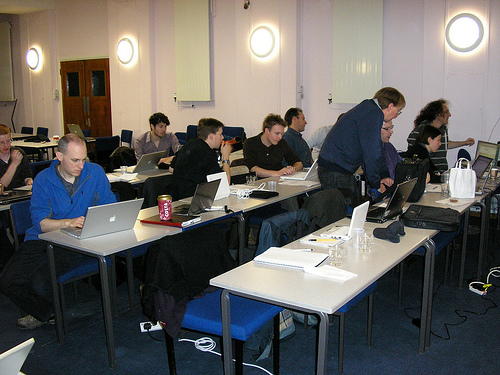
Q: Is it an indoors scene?
A: Yes, it is indoors.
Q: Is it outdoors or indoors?
A: It is indoors.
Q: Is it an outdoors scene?
A: No, it is indoors.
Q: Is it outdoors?
A: No, it is indoors.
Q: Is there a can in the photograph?
A: Yes, there is a can.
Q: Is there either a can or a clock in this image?
A: Yes, there is a can.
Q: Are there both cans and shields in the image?
A: No, there is a can but no shields.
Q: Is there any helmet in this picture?
A: No, there are no helmets.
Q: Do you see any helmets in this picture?
A: No, there are no helmets.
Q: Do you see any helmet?
A: No, there are no helmets.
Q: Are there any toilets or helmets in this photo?
A: No, there are no helmets or toilets.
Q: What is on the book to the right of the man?
A: The can is on the book.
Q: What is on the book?
A: The can is on the book.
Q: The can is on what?
A: The can is on the book.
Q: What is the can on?
A: The can is on the book.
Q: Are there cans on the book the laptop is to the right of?
A: Yes, there is a can on the book.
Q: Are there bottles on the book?
A: No, there is a can on the book.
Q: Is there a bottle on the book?
A: No, there is a can on the book.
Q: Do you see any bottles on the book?
A: No, there is a can on the book.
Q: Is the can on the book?
A: Yes, the can is on the book.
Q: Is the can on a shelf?
A: No, the can is on the book.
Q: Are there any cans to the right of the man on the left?
A: Yes, there is a can to the right of the man.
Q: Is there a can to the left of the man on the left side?
A: No, the can is to the right of the man.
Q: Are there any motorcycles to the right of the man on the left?
A: No, there is a can to the right of the man.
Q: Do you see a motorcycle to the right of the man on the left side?
A: No, there is a can to the right of the man.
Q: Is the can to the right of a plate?
A: No, the can is to the right of the man.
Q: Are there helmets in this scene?
A: No, there are no helmets.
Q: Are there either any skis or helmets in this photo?
A: No, there are no helmets or skis.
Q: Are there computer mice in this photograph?
A: No, there are no computer mice.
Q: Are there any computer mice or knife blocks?
A: No, there are no computer mice or knife blocks.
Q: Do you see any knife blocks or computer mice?
A: No, there are no computer mice or knife blocks.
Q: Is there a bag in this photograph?
A: Yes, there is a bag.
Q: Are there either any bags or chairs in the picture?
A: Yes, there is a bag.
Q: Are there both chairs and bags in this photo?
A: Yes, there are both a bag and a chair.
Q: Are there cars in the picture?
A: No, there are no cars.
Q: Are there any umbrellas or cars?
A: No, there are no cars or umbrellas.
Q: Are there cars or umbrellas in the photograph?
A: No, there are no cars or umbrellas.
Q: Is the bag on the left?
A: No, the bag is on the right of the image.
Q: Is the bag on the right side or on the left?
A: The bag is on the right of the image.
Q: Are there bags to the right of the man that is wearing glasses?
A: Yes, there is a bag to the right of the man.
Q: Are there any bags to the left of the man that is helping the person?
A: No, the bag is to the right of the man.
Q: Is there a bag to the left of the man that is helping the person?
A: No, the bag is to the right of the man.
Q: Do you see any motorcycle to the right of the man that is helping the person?
A: No, there is a bag to the right of the man.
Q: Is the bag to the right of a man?
A: Yes, the bag is to the right of a man.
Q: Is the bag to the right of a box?
A: No, the bag is to the right of a man.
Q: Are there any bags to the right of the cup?
A: No, the bag is to the left of the cup.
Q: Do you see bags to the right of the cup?
A: No, the bag is to the left of the cup.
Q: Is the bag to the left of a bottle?
A: No, the bag is to the left of a cup.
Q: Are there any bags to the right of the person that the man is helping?
A: Yes, there is a bag to the right of the person.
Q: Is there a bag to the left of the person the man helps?
A: No, the bag is to the right of the person.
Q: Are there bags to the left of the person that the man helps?
A: No, the bag is to the right of the person.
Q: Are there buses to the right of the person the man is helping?
A: No, there is a bag to the right of the person.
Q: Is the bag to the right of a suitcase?
A: No, the bag is to the right of a person.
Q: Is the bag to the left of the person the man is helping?
A: No, the bag is to the right of the person.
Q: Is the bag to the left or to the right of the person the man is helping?
A: The bag is to the right of the person.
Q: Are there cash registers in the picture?
A: No, there are no cash registers.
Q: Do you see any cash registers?
A: No, there are no cash registers.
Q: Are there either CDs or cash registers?
A: No, there are no cash registers or cds.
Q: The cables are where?
A: The cables are on the floor.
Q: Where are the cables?
A: The cables are on the floor.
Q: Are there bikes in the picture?
A: No, there are no bikes.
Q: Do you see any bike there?
A: No, there are no bikes.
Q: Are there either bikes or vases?
A: No, there are no bikes or vases.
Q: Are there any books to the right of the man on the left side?
A: Yes, there is a book to the right of the man.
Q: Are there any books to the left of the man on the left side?
A: No, the book is to the right of the man.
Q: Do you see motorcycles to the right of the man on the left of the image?
A: No, there is a book to the right of the man.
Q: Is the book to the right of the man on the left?
A: Yes, the book is to the right of the man.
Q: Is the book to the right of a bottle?
A: No, the book is to the right of the man.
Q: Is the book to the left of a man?
A: No, the book is to the right of a man.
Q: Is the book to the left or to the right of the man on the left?
A: The book is to the right of the man.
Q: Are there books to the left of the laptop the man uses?
A: Yes, there is a book to the left of the laptop.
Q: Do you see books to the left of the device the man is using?
A: Yes, there is a book to the left of the laptop.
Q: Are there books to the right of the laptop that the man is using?
A: No, the book is to the left of the laptop computer.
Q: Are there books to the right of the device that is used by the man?
A: No, the book is to the left of the laptop computer.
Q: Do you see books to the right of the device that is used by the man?
A: No, the book is to the left of the laptop computer.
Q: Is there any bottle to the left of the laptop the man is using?
A: No, there is a book to the left of the laptop.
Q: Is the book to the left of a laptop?
A: Yes, the book is to the left of a laptop.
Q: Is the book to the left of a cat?
A: No, the book is to the left of a laptop.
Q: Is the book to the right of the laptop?
A: No, the book is to the left of the laptop.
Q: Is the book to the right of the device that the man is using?
A: No, the book is to the left of the laptop.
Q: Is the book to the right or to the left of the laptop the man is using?
A: The book is to the left of the laptop.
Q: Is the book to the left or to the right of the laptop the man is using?
A: The book is to the left of the laptop.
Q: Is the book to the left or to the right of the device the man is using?
A: The book is to the left of the laptop.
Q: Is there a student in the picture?
A: Yes, there is a student.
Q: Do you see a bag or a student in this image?
A: Yes, there is a student.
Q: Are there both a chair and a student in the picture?
A: Yes, there are both a student and a chair.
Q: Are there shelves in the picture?
A: No, there are no shelves.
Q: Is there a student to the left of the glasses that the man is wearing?
A: Yes, there is a student to the left of the glasses.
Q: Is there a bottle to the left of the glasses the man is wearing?
A: No, there is a student to the left of the glasses.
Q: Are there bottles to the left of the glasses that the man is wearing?
A: No, there is a student to the left of the glasses.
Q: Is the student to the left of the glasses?
A: Yes, the student is to the left of the glasses.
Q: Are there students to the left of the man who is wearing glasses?
A: Yes, there is a student to the left of the man.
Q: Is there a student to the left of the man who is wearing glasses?
A: Yes, there is a student to the left of the man.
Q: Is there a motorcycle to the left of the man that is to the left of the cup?
A: No, there is a student to the left of the man.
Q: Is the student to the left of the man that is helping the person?
A: Yes, the student is to the left of the man.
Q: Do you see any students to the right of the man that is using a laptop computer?
A: Yes, there is a student to the right of the man.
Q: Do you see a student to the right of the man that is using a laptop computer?
A: Yes, there is a student to the right of the man.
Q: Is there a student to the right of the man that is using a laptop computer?
A: Yes, there is a student to the right of the man.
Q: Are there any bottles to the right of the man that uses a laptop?
A: No, there is a student to the right of the man.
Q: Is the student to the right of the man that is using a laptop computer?
A: Yes, the student is to the right of the man.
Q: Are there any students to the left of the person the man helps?
A: Yes, there is a student to the left of the person.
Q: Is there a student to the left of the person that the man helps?
A: Yes, there is a student to the left of the person.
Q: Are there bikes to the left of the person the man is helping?
A: No, there is a student to the left of the person.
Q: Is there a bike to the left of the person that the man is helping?
A: No, there is a student to the left of the person.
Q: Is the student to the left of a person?
A: Yes, the student is to the left of a person.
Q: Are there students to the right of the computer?
A: Yes, there is a student to the right of the computer.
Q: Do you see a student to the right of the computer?
A: Yes, there is a student to the right of the computer.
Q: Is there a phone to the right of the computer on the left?
A: No, there is a student to the right of the computer.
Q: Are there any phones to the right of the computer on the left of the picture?
A: No, there is a student to the right of the computer.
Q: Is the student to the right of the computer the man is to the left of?
A: Yes, the student is to the right of the computer.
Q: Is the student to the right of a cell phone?
A: No, the student is to the right of the computer.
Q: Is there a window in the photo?
A: Yes, there are windows.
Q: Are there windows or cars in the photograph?
A: Yes, there are windows.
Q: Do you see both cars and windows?
A: No, there are windows but no cars.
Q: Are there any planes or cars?
A: No, there are no cars or planes.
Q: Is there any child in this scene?
A: Yes, there are children.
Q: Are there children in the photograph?
A: Yes, there are children.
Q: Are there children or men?
A: Yes, there are children.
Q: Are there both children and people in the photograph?
A: Yes, there are both children and people.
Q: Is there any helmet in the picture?
A: No, there are no helmets.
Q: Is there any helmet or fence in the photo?
A: No, there are no helmets or fences.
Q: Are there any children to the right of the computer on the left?
A: Yes, there are children to the right of the computer.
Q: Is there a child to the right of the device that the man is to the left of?
A: Yes, there are children to the right of the computer.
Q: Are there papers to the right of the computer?
A: No, there are children to the right of the computer.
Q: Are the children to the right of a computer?
A: Yes, the children are to the right of a computer.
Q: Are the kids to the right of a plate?
A: No, the kids are to the right of a computer.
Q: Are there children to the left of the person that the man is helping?
A: Yes, there are children to the left of the person.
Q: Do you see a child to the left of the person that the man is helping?
A: Yes, there are children to the left of the person.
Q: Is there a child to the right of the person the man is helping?
A: No, the children are to the left of the person.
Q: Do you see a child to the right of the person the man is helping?
A: No, the children are to the left of the person.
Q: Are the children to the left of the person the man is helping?
A: Yes, the children are to the left of the person.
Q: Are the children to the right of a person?
A: No, the children are to the left of a person.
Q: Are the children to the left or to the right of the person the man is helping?
A: The children are to the left of the person.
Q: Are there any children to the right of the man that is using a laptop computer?
A: Yes, there are children to the right of the man.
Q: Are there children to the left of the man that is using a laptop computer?
A: No, the children are to the right of the man.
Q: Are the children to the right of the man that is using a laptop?
A: Yes, the children are to the right of the man.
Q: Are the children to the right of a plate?
A: No, the children are to the right of the man.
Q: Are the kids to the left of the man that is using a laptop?
A: No, the kids are to the right of the man.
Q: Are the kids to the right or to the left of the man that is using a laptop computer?
A: The kids are to the right of the man.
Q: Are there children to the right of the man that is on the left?
A: Yes, there are children to the right of the man.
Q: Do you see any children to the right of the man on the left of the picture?
A: Yes, there are children to the right of the man.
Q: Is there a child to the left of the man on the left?
A: No, the children are to the right of the man.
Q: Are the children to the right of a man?
A: Yes, the children are to the right of a man.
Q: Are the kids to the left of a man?
A: No, the kids are to the right of a man.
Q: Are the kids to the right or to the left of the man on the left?
A: The kids are to the right of the man.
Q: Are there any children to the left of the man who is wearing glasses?
A: Yes, there are children to the left of the man.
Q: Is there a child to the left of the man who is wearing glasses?
A: Yes, there are children to the left of the man.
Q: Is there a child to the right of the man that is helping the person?
A: No, the children are to the left of the man.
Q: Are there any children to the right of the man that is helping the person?
A: No, the children are to the left of the man.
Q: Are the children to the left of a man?
A: Yes, the children are to the left of a man.